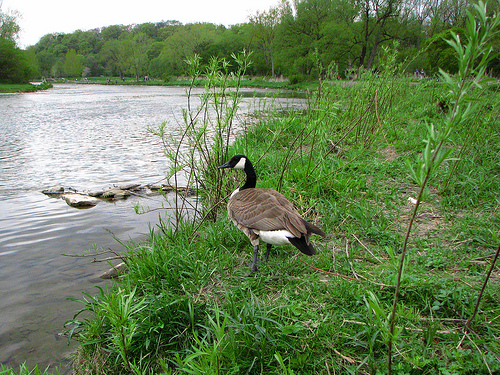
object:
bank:
[75, 76, 497, 368]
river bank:
[0, 75, 319, 94]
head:
[218, 155, 246, 170]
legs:
[243, 230, 273, 268]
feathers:
[260, 222, 309, 256]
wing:
[230, 188, 307, 239]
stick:
[386, 139, 444, 375]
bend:
[6, 80, 347, 369]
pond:
[0, 79, 306, 374]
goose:
[218, 154, 327, 277]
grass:
[54, 0, 500, 375]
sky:
[0, 0, 274, 39]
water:
[0, 82, 312, 375]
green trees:
[0, 1, 42, 84]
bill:
[218, 161, 231, 169]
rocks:
[41, 182, 199, 207]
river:
[0, 74, 312, 374]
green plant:
[130, 46, 256, 223]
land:
[328, 80, 364, 87]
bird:
[218, 155, 327, 278]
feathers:
[286, 234, 317, 256]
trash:
[407, 196, 422, 204]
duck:
[218, 154, 326, 277]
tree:
[62, 48, 85, 80]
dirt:
[385, 142, 403, 163]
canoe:
[29, 81, 44, 85]